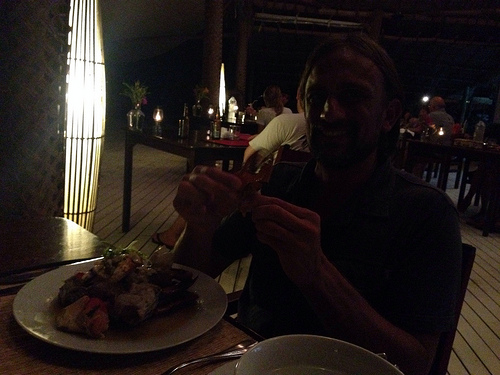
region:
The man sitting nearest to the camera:
[122, 22, 474, 368]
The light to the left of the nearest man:
[41, 0, 117, 240]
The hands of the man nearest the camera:
[167, 162, 327, 267]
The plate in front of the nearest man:
[0, 240, 230, 362]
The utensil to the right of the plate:
[140, 335, 260, 374]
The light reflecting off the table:
[56, 217, 100, 264]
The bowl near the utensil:
[227, 323, 412, 373]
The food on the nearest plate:
[49, 240, 201, 337]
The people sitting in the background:
[111, 44, 482, 244]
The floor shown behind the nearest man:
[94, 126, 499, 372]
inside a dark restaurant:
[3, 3, 491, 369]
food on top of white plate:
[14, 225, 236, 359]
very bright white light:
[58, 0, 123, 244]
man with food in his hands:
[191, 40, 471, 365]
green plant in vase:
[122, 77, 165, 145]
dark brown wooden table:
[2, 210, 282, 372]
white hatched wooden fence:
[0, 17, 70, 234]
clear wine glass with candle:
[144, 100, 169, 142]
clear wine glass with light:
[150, 105, 168, 138]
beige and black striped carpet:
[427, 212, 497, 369]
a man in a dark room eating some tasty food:
[6, 25, 478, 371]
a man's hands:
[174, 165, 327, 285]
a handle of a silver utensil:
[174, 344, 247, 371]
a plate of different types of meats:
[19, 241, 219, 359]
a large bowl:
[229, 332, 402, 373]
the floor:
[146, 165, 174, 204]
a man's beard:
[304, 131, 379, 173]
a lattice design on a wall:
[8, 14, 67, 213]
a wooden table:
[9, 225, 96, 255]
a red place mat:
[219, 136, 251, 147]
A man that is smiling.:
[179, 27, 476, 372]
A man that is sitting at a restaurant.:
[141, 31, 486, 371]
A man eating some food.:
[163, 16, 483, 373]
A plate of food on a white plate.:
[32, 222, 219, 347]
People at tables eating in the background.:
[115, 48, 499, 254]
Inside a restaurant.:
[9, 5, 491, 357]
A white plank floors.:
[90, 117, 499, 369]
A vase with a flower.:
[111, 69, 163, 135]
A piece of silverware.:
[149, 332, 276, 370]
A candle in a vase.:
[139, 100, 174, 127]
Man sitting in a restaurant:
[166, 22, 469, 371]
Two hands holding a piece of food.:
[164, 121, 330, 289]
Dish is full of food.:
[10, 241, 238, 358]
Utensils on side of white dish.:
[3, 242, 255, 372]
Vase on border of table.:
[114, 76, 154, 137]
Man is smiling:
[166, 24, 467, 373]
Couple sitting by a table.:
[397, 91, 476, 181]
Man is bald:
[412, 89, 460, 148]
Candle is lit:
[147, 100, 169, 142]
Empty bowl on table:
[232, 328, 403, 373]